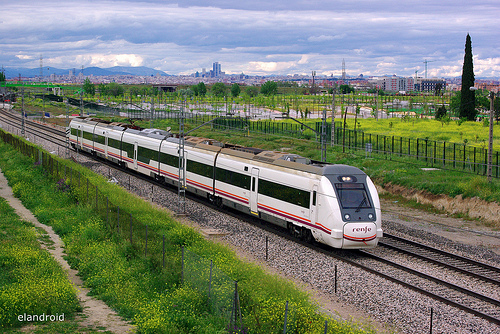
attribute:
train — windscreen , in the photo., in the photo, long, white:
[65, 114, 384, 254]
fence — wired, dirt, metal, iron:
[2, 96, 498, 333]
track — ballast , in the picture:
[7, 107, 497, 328]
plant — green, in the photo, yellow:
[6, 138, 308, 332]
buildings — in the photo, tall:
[10, 66, 498, 98]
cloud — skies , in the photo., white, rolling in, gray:
[4, 1, 497, 100]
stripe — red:
[67, 134, 377, 250]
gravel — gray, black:
[4, 109, 497, 332]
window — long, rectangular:
[72, 124, 318, 232]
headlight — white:
[338, 171, 379, 227]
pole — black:
[7, 74, 193, 227]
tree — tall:
[457, 30, 481, 136]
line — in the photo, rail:
[394, 223, 457, 333]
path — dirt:
[394, 221, 490, 328]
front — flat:
[324, 163, 385, 254]